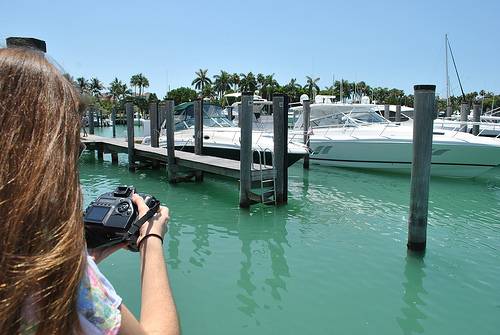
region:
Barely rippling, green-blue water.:
[250, 237, 451, 323]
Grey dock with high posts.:
[89, 108, 333, 183]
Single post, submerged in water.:
[402, 82, 432, 271]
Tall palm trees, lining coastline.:
[85, 67, 396, 119]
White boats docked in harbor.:
[185, 96, 499, 168]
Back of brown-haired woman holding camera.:
[0, 32, 200, 334]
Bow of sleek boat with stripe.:
[320, 107, 499, 182]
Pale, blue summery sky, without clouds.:
[123, 19, 381, 59]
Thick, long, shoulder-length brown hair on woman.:
[5, 57, 93, 334]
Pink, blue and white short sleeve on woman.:
[80, 274, 120, 331]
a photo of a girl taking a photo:
[0, 35, 212, 331]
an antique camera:
[68, 164, 193, 259]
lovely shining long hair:
[0, 26, 102, 333]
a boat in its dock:
[131, 105, 309, 182]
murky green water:
[0, 42, 498, 334]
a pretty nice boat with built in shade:
[253, 97, 497, 178]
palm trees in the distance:
[58, 61, 249, 128]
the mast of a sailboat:
[428, 25, 473, 161]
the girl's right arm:
[37, 180, 184, 333]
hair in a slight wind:
[0, 33, 175, 333]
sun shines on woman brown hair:
[6, 46, 86, 322]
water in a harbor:
[199, 198, 381, 325]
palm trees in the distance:
[191, 68, 321, 97]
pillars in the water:
[415, 85, 430, 272]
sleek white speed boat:
[301, 96, 490, 181]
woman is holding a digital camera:
[84, 182, 159, 257]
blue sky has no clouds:
[28, 3, 417, 38]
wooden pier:
[109, 139, 281, 168]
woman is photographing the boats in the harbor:
[8, 44, 186, 331]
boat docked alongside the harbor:
[154, 101, 316, 177]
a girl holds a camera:
[2, 45, 186, 332]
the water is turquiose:
[67, 122, 497, 334]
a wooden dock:
[78, 106, 290, 209]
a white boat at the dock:
[131, 97, 308, 163]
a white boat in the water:
[282, 97, 498, 178]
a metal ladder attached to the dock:
[255, 145, 284, 205]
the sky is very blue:
[1, 0, 497, 92]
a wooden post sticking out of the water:
[402, 83, 437, 254]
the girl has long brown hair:
[0, 40, 87, 334]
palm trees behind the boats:
[56, 67, 498, 105]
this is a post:
[408, 83, 439, 260]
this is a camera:
[84, 182, 142, 250]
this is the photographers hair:
[0, 33, 86, 332]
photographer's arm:
[134, 198, 177, 333]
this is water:
[178, 206, 407, 333]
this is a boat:
[312, 98, 498, 182]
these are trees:
[85, 70, 400, 97]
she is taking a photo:
[1, 51, 176, 333]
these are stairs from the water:
[255, 146, 281, 216]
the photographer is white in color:
[139, 213, 181, 328]